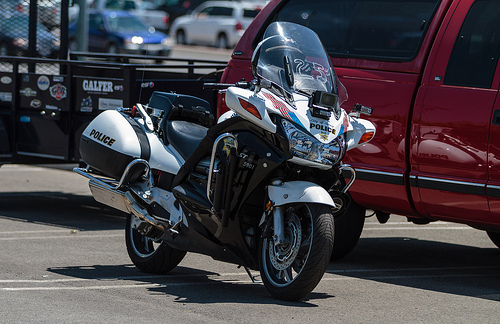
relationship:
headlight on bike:
[274, 112, 341, 169] [76, 21, 374, 300]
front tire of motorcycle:
[254, 179, 334, 302] [111, 88, 430, 247]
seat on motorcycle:
[114, 75, 224, 160] [113, 99, 469, 259]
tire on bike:
[121, 200, 193, 278] [76, 21, 374, 300]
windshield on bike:
[253, 20, 335, 100] [76, 21, 374, 300]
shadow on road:
[0, 185, 125, 230] [2, 160, 499, 322]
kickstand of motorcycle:
[238, 262, 256, 282] [98, 63, 448, 292]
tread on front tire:
[314, 225, 334, 273] [254, 179, 336, 302]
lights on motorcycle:
[308, 89, 343, 127] [118, 93, 265, 233]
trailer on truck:
[24, 25, 225, 189] [128, 30, 446, 156]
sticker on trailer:
[71, 80, 163, 139] [3, 2, 226, 198]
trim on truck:
[368, 161, 489, 198] [96, 0, 488, 302]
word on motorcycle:
[88, 127, 115, 146] [88, 112, 204, 213]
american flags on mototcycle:
[260, 74, 308, 131] [62, 93, 245, 246]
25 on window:
[291, 50, 333, 87] [276, 37, 415, 77]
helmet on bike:
[219, 61, 354, 131] [85, 56, 496, 301]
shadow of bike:
[68, 245, 275, 297] [76, 21, 374, 300]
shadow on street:
[68, 245, 275, 297] [46, 228, 241, 319]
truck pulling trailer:
[289, 1, 466, 207] [2, 3, 237, 187]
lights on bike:
[236, 97, 262, 122] [76, 21, 374, 300]